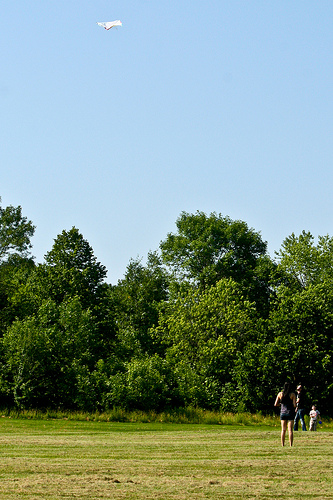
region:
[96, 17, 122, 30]
white kite in sky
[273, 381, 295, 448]
woman standing on grass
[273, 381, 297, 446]
woman wearing black shorts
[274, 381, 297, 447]
woman wearing black tank top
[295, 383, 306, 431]
man flying white kite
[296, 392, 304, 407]
black cotton tee shirt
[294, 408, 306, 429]
dark blue denim jeans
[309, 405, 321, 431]
person standing on field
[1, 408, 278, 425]
weeds next to trees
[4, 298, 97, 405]
tree with green leaves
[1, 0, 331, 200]
clear blue daytime sky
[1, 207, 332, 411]
grren leaves of trees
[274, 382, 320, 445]
three standing people outdoors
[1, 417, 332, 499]
green grass on surface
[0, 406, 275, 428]
line of tall grass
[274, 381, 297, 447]
back of woman in shorts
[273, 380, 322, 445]
two adults and a child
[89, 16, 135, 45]
kite in blue sky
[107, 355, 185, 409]
leaves on bush branches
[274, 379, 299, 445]
woman in sleeveless top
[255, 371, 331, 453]
people in an open field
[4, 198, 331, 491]
trees behind an open field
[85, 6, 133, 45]
a kite in the sky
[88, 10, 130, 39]
kite is white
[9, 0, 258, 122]
a kite in the blue sky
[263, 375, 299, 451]
woman has long hair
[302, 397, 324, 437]
a kid on green grass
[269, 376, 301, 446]
woman wears a top tank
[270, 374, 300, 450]
woman combs in a pony tail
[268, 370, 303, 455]
woman wears shorts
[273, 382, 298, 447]
young woman wearing blue jean shorts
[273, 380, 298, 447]
young woman standing in grassy field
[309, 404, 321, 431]
young child wearing gray shirt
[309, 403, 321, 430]
young child standing in grassy field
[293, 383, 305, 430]
man wearing black shirt looking at sky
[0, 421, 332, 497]
large field with brown grass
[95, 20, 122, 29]
kite flying high in sky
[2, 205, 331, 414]
row of large trees in background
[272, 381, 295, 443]
woman wearing sleeveless shirt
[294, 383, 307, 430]
man looking up at sky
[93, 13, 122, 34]
white kite in the air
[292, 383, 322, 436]
two people standing by trees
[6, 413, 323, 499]
grassy area people are standing on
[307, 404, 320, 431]
person wearing gray clothes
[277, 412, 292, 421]
shorts of woman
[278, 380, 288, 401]
long black hair of woman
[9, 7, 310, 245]
sky kite is flying in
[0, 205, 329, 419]
trees lining grassy area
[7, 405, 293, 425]
grass growing along tree line